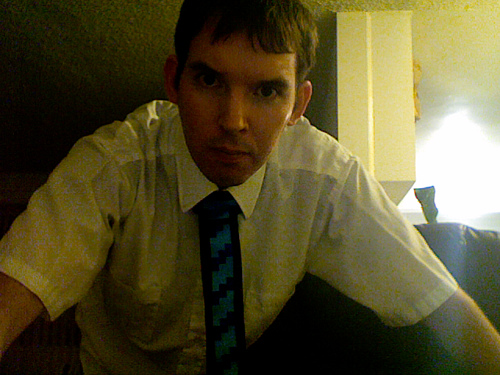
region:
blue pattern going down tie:
[206, 221, 238, 258]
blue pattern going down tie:
[202, 254, 237, 296]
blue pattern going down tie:
[207, 277, 240, 336]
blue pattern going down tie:
[197, 240, 227, 276]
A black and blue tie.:
[180, 196, 277, 374]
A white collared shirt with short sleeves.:
[18, 106, 458, 373]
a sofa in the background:
[284, 215, 498, 357]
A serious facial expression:
[186, 41, 296, 168]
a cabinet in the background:
[306, 0, 431, 212]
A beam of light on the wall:
[420, 116, 498, 257]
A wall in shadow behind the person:
[19, 11, 481, 201]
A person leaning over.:
[5, 9, 482, 372]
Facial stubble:
[182, 129, 279, 184]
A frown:
[195, 132, 295, 177]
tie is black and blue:
[181, 189, 261, 374]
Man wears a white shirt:
[0, 4, 499, 373]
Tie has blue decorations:
[184, 187, 259, 373]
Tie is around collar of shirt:
[190, 182, 254, 373]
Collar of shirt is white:
[174, 173, 276, 220]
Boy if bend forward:
[8, 6, 498, 371]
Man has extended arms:
[7, 1, 495, 373]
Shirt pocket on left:
[94, 266, 172, 351]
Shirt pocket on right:
[234, 282, 299, 344]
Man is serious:
[111, 1, 349, 215]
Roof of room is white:
[11, 6, 153, 91]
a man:
[21, 12, 498, 347]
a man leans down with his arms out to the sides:
[21, 4, 493, 337]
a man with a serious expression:
[22, 5, 474, 372]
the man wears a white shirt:
[21, 11, 498, 368]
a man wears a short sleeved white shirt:
[17, 10, 493, 373]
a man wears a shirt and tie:
[17, 7, 499, 364]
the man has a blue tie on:
[24, 4, 498, 372]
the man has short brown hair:
[31, 8, 471, 373]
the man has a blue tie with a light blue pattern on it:
[24, 8, 464, 371]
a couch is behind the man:
[46, 185, 498, 367]